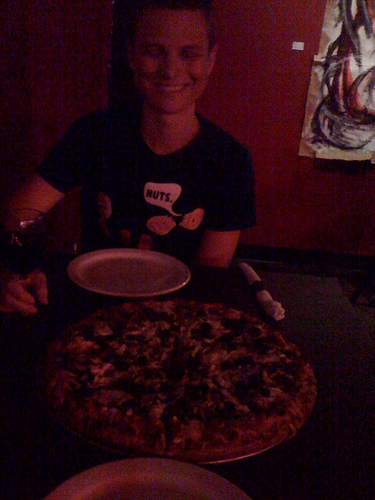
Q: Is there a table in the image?
A: Yes, there is a table.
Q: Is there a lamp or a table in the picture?
A: Yes, there is a table.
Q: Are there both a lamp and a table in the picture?
A: No, there is a table but no lamps.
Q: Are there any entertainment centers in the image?
A: No, there are no entertainment centers.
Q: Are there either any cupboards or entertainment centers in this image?
A: No, there are no entertainment centers or cupboards.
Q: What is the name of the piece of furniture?
A: The piece of furniture is a table.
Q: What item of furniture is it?
A: The piece of furniture is a table.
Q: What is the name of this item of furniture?
A: This is a table.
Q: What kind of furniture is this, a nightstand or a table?
A: This is a table.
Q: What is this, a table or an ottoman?
A: This is a table.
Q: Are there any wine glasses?
A: Yes, there is a wine glass.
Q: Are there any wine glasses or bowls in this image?
A: Yes, there is a wine glass.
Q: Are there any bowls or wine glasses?
A: Yes, there is a wine glass.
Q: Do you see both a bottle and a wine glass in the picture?
A: No, there is a wine glass but no bottles.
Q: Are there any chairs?
A: No, there are no chairs.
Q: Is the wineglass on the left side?
A: Yes, the wineglass is on the left of the image.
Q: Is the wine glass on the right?
A: No, the wine glass is on the left of the image.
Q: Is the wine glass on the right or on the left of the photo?
A: The wine glass is on the left of the image.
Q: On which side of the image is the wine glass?
A: The wine glass is on the left of the image.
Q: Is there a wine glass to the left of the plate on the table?
A: Yes, there is a wine glass to the left of the plate.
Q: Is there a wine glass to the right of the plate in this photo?
A: No, the wine glass is to the left of the plate.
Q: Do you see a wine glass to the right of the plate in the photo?
A: No, the wine glass is to the left of the plate.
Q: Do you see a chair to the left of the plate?
A: No, there is a wine glass to the left of the plate.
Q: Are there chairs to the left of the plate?
A: No, there is a wine glass to the left of the plate.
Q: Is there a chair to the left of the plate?
A: No, there is a wine glass to the left of the plate.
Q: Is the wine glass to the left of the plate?
A: Yes, the wine glass is to the left of the plate.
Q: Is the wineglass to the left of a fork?
A: No, the wineglass is to the left of the plate.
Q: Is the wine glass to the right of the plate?
A: No, the wine glass is to the left of the plate.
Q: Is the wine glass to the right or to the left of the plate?
A: The wine glass is to the left of the plate.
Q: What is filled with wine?
A: The wineglass is filled with wine.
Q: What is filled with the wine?
A: The wineglass is filled with wine.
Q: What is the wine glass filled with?
A: The wine glass is filled with wine.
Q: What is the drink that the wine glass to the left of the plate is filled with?
A: The drink is wine.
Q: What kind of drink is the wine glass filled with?
A: The wineglass is filled with wine.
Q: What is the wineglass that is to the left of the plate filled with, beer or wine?
A: The wineglass is filled with wine.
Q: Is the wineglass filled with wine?
A: Yes, the wineglass is filled with wine.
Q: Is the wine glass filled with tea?
A: No, the wine glass is filled with wine.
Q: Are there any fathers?
A: No, there are no fathers.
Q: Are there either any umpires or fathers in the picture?
A: No, there are no fathers or umpires.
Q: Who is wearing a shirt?
A: The man is wearing a shirt.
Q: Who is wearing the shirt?
A: The man is wearing a shirt.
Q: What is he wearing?
A: The man is wearing a shirt.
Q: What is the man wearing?
A: The man is wearing a shirt.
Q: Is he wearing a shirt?
A: Yes, the man is wearing a shirt.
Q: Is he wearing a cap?
A: No, the man is wearing a shirt.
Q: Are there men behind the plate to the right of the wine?
A: Yes, there is a man behind the plate.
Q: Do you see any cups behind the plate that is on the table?
A: No, there is a man behind the plate.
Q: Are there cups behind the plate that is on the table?
A: No, there is a man behind the plate.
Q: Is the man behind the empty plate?
A: Yes, the man is behind the plate.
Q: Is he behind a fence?
A: No, the man is behind the plate.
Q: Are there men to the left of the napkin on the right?
A: Yes, there is a man to the left of the napkin.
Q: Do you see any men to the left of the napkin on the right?
A: Yes, there is a man to the left of the napkin.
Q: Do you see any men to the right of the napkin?
A: No, the man is to the left of the napkin.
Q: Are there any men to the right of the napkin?
A: No, the man is to the left of the napkin.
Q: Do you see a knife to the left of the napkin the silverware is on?
A: No, there is a man to the left of the napkin.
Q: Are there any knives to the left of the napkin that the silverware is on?
A: No, there is a man to the left of the napkin.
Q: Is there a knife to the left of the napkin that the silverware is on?
A: No, there is a man to the left of the napkin.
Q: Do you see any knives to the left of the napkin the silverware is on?
A: No, there is a man to the left of the napkin.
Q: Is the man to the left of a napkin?
A: Yes, the man is to the left of a napkin.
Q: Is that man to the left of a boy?
A: No, the man is to the left of a napkin.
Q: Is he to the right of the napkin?
A: No, the man is to the left of the napkin.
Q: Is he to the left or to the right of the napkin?
A: The man is to the left of the napkin.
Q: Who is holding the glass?
A: The man is holding the glass.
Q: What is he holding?
A: The man is holding the glass.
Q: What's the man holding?
A: The man is holding the glass.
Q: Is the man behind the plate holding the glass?
A: Yes, the man is holding the glass.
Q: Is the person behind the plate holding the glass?
A: Yes, the man is holding the glass.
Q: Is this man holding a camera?
A: No, the man is holding the glass.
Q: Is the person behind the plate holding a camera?
A: No, the man is holding the glass.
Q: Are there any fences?
A: No, there are no fences.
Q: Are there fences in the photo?
A: No, there are no fences.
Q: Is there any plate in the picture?
A: Yes, there is a plate.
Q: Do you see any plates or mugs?
A: Yes, there is a plate.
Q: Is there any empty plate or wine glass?
A: Yes, there is an empty plate.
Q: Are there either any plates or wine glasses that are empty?
A: Yes, the plate is empty.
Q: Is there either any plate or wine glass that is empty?
A: Yes, the plate is empty.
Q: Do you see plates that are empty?
A: Yes, there is an empty plate.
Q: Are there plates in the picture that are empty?
A: Yes, there is a plate that is empty.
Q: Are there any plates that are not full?
A: Yes, there is a empty plate.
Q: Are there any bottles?
A: No, there are no bottles.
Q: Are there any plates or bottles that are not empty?
A: No, there is a plate but it is empty.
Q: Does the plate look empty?
A: Yes, the plate is empty.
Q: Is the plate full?
A: No, the plate is empty.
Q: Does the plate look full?
A: No, the plate is empty.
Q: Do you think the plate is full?
A: No, the plate is empty.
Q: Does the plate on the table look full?
A: No, the plate is empty.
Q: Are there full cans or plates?
A: No, there is a plate but it is empty.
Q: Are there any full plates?
A: No, there is a plate but it is empty.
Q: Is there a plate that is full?
A: No, there is a plate but it is empty.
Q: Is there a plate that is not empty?
A: No, there is a plate but it is empty.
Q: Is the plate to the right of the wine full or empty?
A: The plate is empty.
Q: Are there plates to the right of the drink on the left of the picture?
A: Yes, there is a plate to the right of the wine.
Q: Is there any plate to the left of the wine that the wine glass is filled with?
A: No, the plate is to the right of the wine.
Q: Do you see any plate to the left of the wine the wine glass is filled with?
A: No, the plate is to the right of the wine.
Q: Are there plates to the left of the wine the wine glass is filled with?
A: No, the plate is to the right of the wine.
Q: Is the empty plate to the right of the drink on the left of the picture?
A: Yes, the plate is to the right of the wine.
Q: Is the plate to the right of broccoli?
A: No, the plate is to the right of the wine.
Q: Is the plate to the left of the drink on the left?
A: No, the plate is to the right of the wine.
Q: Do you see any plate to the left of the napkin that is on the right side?
A: Yes, there is a plate to the left of the napkin.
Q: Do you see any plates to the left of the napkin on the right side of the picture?
A: Yes, there is a plate to the left of the napkin.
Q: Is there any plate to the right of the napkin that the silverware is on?
A: No, the plate is to the left of the napkin.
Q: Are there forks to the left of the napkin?
A: No, there is a plate to the left of the napkin.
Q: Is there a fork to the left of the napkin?
A: No, there is a plate to the left of the napkin.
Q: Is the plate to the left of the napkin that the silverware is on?
A: Yes, the plate is to the left of the napkin.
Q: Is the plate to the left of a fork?
A: No, the plate is to the left of the napkin.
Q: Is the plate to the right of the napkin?
A: No, the plate is to the left of the napkin.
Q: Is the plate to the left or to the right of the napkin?
A: The plate is to the left of the napkin.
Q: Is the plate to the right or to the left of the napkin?
A: The plate is to the left of the napkin.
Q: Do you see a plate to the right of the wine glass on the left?
A: Yes, there is a plate to the right of the wine glass.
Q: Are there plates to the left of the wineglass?
A: No, the plate is to the right of the wineglass.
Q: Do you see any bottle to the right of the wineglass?
A: No, there is a plate to the right of the wineglass.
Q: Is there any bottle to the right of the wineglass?
A: No, there is a plate to the right of the wineglass.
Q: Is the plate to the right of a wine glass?
A: Yes, the plate is to the right of a wine glass.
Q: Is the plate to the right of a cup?
A: No, the plate is to the right of a wine glass.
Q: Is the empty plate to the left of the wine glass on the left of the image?
A: No, the plate is to the right of the wine glass.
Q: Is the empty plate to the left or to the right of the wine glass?
A: The plate is to the right of the wine glass.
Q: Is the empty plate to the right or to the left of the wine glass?
A: The plate is to the right of the wine glass.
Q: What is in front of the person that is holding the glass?
A: The plate is in front of the man.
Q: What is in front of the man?
A: The plate is in front of the man.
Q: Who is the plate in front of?
A: The plate is in front of the man.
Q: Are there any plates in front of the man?
A: Yes, there is a plate in front of the man.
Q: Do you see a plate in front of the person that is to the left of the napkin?
A: Yes, there is a plate in front of the man.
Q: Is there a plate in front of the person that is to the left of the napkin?
A: Yes, there is a plate in front of the man.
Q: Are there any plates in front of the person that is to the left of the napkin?
A: Yes, there is a plate in front of the man.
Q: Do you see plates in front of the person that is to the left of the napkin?
A: Yes, there is a plate in front of the man.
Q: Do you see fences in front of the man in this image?
A: No, there is a plate in front of the man.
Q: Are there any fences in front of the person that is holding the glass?
A: No, there is a plate in front of the man.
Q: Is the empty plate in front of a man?
A: Yes, the plate is in front of a man.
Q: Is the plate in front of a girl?
A: No, the plate is in front of a man.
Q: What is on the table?
A: The plate is on the table.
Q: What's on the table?
A: The plate is on the table.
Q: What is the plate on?
A: The plate is on the table.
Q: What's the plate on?
A: The plate is on the table.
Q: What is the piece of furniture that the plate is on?
A: The piece of furniture is a table.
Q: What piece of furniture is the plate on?
A: The plate is on the table.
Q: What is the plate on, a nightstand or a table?
A: The plate is on a table.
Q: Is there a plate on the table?
A: Yes, there is a plate on the table.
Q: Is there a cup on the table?
A: No, there is a plate on the table.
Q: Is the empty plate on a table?
A: Yes, the plate is on a table.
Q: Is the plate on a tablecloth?
A: No, the plate is on a table.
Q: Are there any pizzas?
A: Yes, there is a pizza.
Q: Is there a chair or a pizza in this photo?
A: Yes, there is a pizza.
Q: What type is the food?
A: The food is a pizza.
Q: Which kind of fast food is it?
A: The food is a pizza.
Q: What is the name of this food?
A: This is a pizza.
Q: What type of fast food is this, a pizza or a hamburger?
A: This is a pizza.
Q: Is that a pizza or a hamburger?
A: That is a pizza.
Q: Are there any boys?
A: No, there are no boys.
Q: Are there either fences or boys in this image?
A: No, there are no boys or fences.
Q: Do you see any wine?
A: Yes, there is wine.